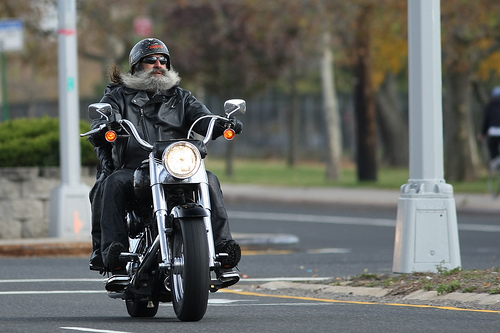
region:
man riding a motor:
[98, 14, 233, 262]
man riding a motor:
[72, 35, 279, 319]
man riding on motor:
[12, 18, 249, 316]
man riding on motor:
[88, 38, 228, 279]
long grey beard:
[102, 65, 182, 93]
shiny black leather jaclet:
[85, 71, 238, 170]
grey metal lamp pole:
[388, 0, 466, 273]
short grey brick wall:
[0, 163, 117, 248]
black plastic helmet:
[120, 33, 179, 70]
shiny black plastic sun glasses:
[139, 51, 167, 68]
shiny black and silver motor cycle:
[72, 91, 250, 323]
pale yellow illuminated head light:
[156, 136, 207, 183]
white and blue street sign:
[2, 14, 32, 59]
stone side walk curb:
[1, 234, 304, 259]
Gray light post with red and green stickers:
[57, 0, 89, 240]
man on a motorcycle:
[87, 38, 245, 323]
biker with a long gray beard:
[87, 33, 245, 321]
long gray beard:
[110, 65, 180, 91]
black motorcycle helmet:
[126, 38, 173, 67]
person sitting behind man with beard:
[89, 67, 124, 267]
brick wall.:
[2, 170, 105, 238]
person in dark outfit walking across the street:
[480, 85, 498, 187]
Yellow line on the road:
[222, 288, 499, 313]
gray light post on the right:
[388, 2, 463, 272]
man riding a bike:
[70, 32, 260, 274]